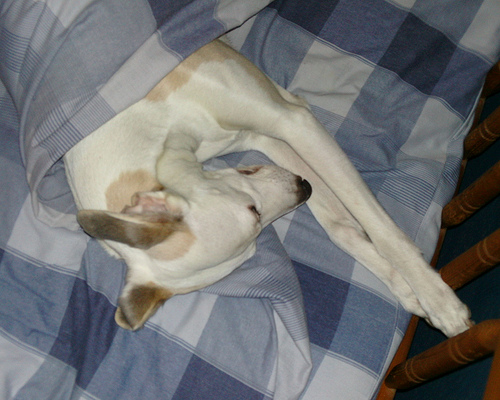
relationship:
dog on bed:
[59, 35, 472, 340] [3, 1, 499, 399]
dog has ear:
[59, 35, 472, 340] [68, 191, 186, 252]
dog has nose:
[59, 35, 472, 340] [300, 179, 312, 201]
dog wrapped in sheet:
[59, 35, 472, 340] [0, 0, 499, 400]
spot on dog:
[99, 166, 163, 214] [59, 35, 472, 340]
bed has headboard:
[3, 1, 499, 399] [371, 59, 496, 399]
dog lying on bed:
[59, 35, 472, 340] [3, 1, 499, 399]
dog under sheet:
[59, 35, 472, 340] [2, 3, 278, 234]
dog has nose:
[59, 35, 472, 340] [296, 173, 315, 203]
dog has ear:
[59, 35, 472, 340] [113, 277, 174, 335]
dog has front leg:
[59, 35, 472, 340] [240, 79, 473, 338]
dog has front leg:
[59, 35, 472, 340] [245, 135, 436, 329]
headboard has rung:
[371, 59, 496, 399] [441, 160, 499, 238]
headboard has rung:
[371, 59, 496, 399] [428, 227, 499, 293]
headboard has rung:
[371, 59, 496, 399] [384, 317, 498, 393]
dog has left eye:
[59, 35, 472, 340] [247, 206, 262, 218]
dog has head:
[59, 35, 472, 340] [76, 160, 311, 335]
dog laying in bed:
[59, 35, 472, 340] [3, 1, 499, 399]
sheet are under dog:
[0, 0, 499, 400] [59, 35, 472, 340]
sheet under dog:
[211, 0, 499, 400] [59, 35, 472, 340]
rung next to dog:
[441, 160, 499, 238] [59, 35, 472, 340]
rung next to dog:
[428, 227, 499, 293] [59, 35, 472, 340]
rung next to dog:
[384, 317, 498, 393] [59, 35, 472, 340]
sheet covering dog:
[2, 3, 278, 234] [59, 35, 472, 340]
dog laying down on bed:
[59, 35, 472, 340] [3, 1, 499, 399]